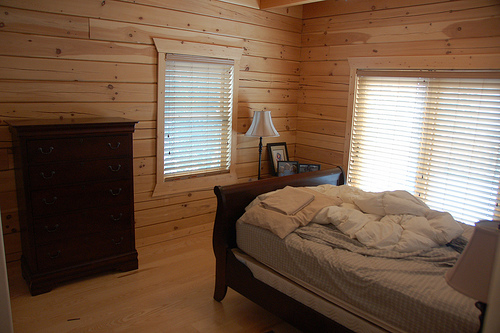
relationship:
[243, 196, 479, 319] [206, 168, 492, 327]
sheets are piled on bed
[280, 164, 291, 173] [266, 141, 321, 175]
pictures are in frames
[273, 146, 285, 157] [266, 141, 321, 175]
pictures are in frames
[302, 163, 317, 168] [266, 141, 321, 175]
pictures are in frames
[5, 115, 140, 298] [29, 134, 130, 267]
dresser has drawers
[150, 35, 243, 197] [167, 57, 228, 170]
window has blinds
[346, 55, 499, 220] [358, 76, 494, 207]
window has blinds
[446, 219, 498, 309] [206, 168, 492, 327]
lamp shade near bed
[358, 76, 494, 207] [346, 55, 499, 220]
blinds cover window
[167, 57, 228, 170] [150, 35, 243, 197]
blinds cover window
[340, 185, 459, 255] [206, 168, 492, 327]
comforter on bed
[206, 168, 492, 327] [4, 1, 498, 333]
bed in bedroom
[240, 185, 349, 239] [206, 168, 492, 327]
pillow on bed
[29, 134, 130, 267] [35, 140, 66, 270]
drawers have handles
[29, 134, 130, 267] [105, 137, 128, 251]
drawers have handles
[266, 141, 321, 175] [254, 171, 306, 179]
frames are on night table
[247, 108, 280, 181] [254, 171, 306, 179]
lamp on night table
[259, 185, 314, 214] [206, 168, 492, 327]
pillow case on bed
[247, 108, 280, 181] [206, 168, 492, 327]
lamp near bed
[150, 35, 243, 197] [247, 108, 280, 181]
window next to lamp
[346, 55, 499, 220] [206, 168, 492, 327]
window near bed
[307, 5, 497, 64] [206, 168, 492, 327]
walls are near bed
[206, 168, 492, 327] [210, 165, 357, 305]
bed has footboard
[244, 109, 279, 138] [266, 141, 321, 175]
lamp shade near frames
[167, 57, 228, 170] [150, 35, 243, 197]
blinds are on window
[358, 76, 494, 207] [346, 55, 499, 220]
blinds are on window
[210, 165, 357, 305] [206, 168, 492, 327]
footboard on bed